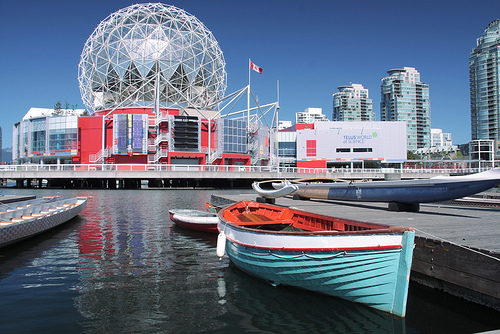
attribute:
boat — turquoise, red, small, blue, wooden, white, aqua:
[215, 199, 416, 318]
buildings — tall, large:
[333, 17, 500, 145]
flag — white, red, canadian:
[250, 60, 265, 74]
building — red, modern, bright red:
[10, 102, 267, 165]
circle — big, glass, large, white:
[77, 3, 229, 109]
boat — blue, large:
[281, 172, 500, 212]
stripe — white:
[217, 221, 402, 249]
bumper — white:
[172, 214, 218, 227]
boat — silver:
[1, 190, 96, 245]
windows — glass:
[46, 119, 79, 152]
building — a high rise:
[470, 16, 499, 139]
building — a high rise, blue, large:
[380, 64, 433, 152]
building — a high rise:
[331, 81, 375, 119]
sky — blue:
[1, 1, 499, 145]